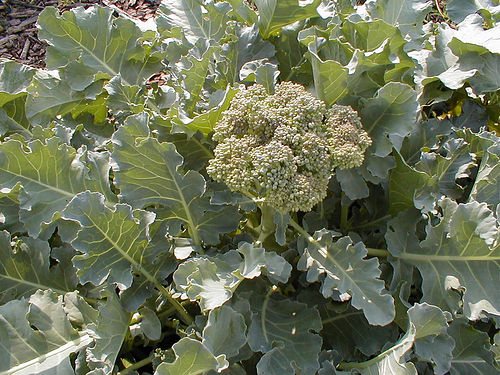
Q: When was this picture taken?
A: Daytime.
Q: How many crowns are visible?
A: 1.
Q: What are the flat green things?
A: Leaves.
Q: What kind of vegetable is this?
A: Broccoli.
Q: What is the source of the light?
A: Sun.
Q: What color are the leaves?
A: Green.